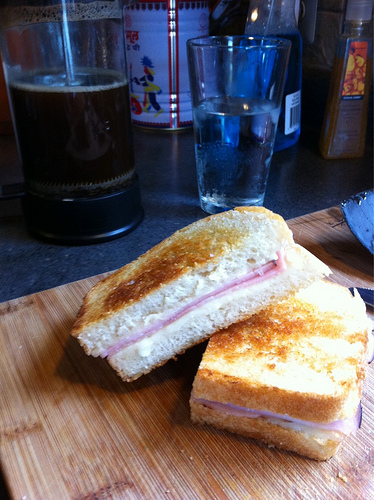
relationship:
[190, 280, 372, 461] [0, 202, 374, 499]
sandwich on board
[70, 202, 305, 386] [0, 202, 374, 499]
sandwich on board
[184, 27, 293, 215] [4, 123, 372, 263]
glass on table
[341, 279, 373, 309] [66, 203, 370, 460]
knife next to sandwich